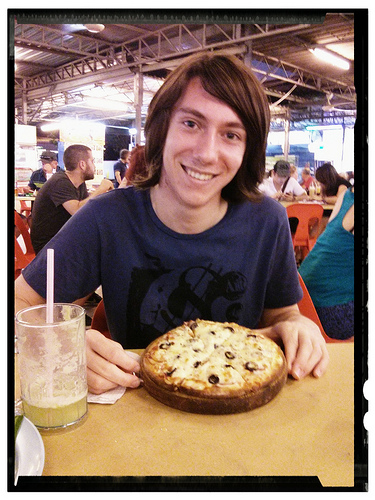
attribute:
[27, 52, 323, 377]
shirt — black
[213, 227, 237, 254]
shirt — black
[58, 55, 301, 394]
person — smiling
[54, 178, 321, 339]
shirt — black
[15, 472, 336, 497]
laptop — black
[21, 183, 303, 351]
t-shirt — blue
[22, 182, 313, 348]
shirt — black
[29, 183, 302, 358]
shirt — black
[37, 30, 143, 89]
railings — metal